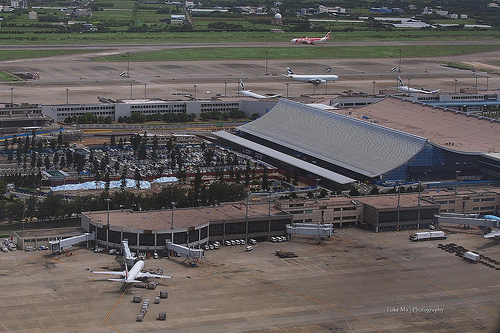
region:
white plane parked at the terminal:
[90, 256, 173, 290]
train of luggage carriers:
[135, 298, 152, 322]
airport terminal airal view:
[81, 186, 498, 251]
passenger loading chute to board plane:
[167, 241, 207, 261]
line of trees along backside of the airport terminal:
[3, 181, 248, 220]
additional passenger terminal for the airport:
[3, 93, 269, 125]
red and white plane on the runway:
[290, 31, 331, 46]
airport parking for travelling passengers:
[4, 138, 248, 183]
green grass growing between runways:
[119, 43, 482, 56]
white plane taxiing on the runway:
[281, 64, 341, 86]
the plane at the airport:
[87, 257, 172, 288]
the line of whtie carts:
[204, 232, 295, 254]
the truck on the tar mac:
[406, 228, 449, 243]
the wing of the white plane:
[88, 268, 128, 273]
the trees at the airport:
[4, 131, 118, 173]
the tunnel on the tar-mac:
[285, 220, 334, 241]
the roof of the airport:
[227, 95, 497, 187]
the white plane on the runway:
[273, 60, 347, 87]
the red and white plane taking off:
[290, 29, 335, 50]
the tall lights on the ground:
[7, 80, 75, 105]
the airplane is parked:
[97, 240, 162, 306]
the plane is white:
[86, 241, 180, 318]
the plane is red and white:
[282, 17, 343, 67]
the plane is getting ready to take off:
[273, 19, 347, 64]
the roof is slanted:
[245, 79, 470, 177]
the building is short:
[61, 187, 301, 269]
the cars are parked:
[194, 231, 291, 250]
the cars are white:
[186, 213, 278, 275]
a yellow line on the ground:
[87, 283, 131, 325]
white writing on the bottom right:
[365, 293, 452, 325]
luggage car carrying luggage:
[136, 298, 150, 322]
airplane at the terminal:
[95, 239, 172, 289]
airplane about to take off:
[280, 64, 340, 87]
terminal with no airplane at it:
[287, 219, 337, 241]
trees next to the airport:
[0, 183, 255, 225]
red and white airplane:
[291, 31, 333, 46]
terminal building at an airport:
[78, 187, 498, 255]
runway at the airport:
[1, 39, 497, 94]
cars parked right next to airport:
[27, 242, 51, 252]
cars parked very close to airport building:
[195, 235, 292, 254]